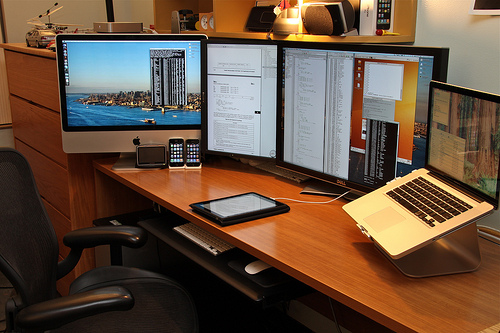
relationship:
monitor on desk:
[54, 32, 208, 155] [89, 153, 499, 332]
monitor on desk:
[200, 37, 282, 164] [89, 153, 499, 332]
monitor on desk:
[279, 40, 450, 194] [89, 153, 499, 332]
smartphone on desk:
[135, 144, 168, 168] [89, 153, 499, 332]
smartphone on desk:
[168, 136, 186, 168] [89, 153, 499, 332]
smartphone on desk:
[183, 136, 201, 168] [89, 153, 499, 332]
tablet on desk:
[189, 191, 291, 226] [89, 153, 499, 332]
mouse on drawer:
[245, 258, 270, 277] [137, 211, 287, 303]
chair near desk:
[0, 145, 201, 332] [89, 153, 499, 332]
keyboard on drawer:
[173, 220, 235, 258] [137, 211, 287, 303]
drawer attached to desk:
[137, 211, 287, 303] [89, 153, 499, 332]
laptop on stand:
[341, 79, 499, 260] [372, 219, 483, 279]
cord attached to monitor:
[273, 190, 351, 204] [279, 40, 450, 194]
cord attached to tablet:
[273, 190, 351, 204] [189, 191, 291, 226]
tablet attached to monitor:
[189, 191, 291, 226] [279, 40, 450, 194]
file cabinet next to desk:
[1, 41, 97, 299] [89, 153, 499, 332]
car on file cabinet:
[23, 28, 56, 50] [1, 41, 97, 299]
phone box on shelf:
[358, 0, 395, 36] [150, 0, 419, 45]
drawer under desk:
[137, 211, 287, 303] [89, 153, 499, 332]